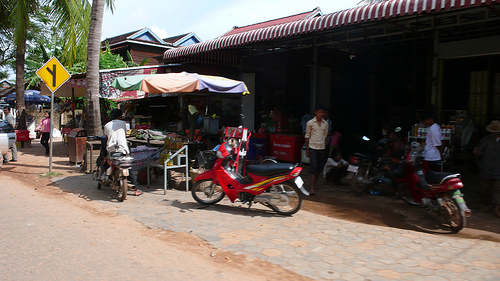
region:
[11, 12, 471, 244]
bikers and motorcycles in front of markets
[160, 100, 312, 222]
red motorcycle parked in front of display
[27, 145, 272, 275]
dirt separating different pavements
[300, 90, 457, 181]
people in light-colored shirts standing in dark shade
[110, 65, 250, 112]
colorful draped fabric covering produce stand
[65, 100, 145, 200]
person on motorbike facing stall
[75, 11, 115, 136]
curved trunk of palm tree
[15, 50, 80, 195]
yellow and black traffic sign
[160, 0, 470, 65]
red and white stripes on edge of awning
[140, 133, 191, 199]
geometric side panel of table holding merchandise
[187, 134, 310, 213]
red and black scooter in center of picture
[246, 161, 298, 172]
black seat of scooter in center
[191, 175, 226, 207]
front tire of scooter in center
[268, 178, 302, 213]
back tire of scooter in center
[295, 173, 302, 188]
license plate of scooter in center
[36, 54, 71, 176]
yellow sign on a pole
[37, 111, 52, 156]
person in pink shirt behind yellow sign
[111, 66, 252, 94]
orange, blue and green umbrella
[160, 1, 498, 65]
long red and white awning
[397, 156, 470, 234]
scooter in shadow on right of photo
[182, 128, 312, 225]
Red scooter parked on the sidewalk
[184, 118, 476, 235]
Two red scooters parked on the street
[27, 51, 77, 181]
Yellow street sign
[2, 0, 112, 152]
Two palm trees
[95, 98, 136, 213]
Man on a scooter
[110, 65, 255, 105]
Multicolored umbrella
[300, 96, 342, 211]
Man walking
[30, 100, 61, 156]
Woman wearing a pink shirt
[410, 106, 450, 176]
Man wearing a white shirt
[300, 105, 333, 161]
Man wearing a yellow button up shirt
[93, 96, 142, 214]
person riding motor bike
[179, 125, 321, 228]
red and black motor bike parked on the street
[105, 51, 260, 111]
multicolored cloth umbrella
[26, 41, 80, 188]
yellow street sign on metal pole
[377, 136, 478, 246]
red and black motorcycle parked on road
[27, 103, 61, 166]
person wearing pink shirt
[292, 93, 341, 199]
person wearing white shirt and black pants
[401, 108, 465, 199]
person wearing white shirt and black pants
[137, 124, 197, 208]
blue chair sitting on street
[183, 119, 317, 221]
Red motorcycle parked on side street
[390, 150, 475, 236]
Red motorcycle with black sit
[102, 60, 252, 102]
Canopy of parasol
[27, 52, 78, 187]
Street sign on street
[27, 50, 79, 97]
Street sign is rombus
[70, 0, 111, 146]
Trunk of tree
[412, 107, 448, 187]
Person wearing white shirt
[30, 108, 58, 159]
Woman wearing pink sweter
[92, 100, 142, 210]
Person driving a bike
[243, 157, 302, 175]
Sit of motorcycle is black